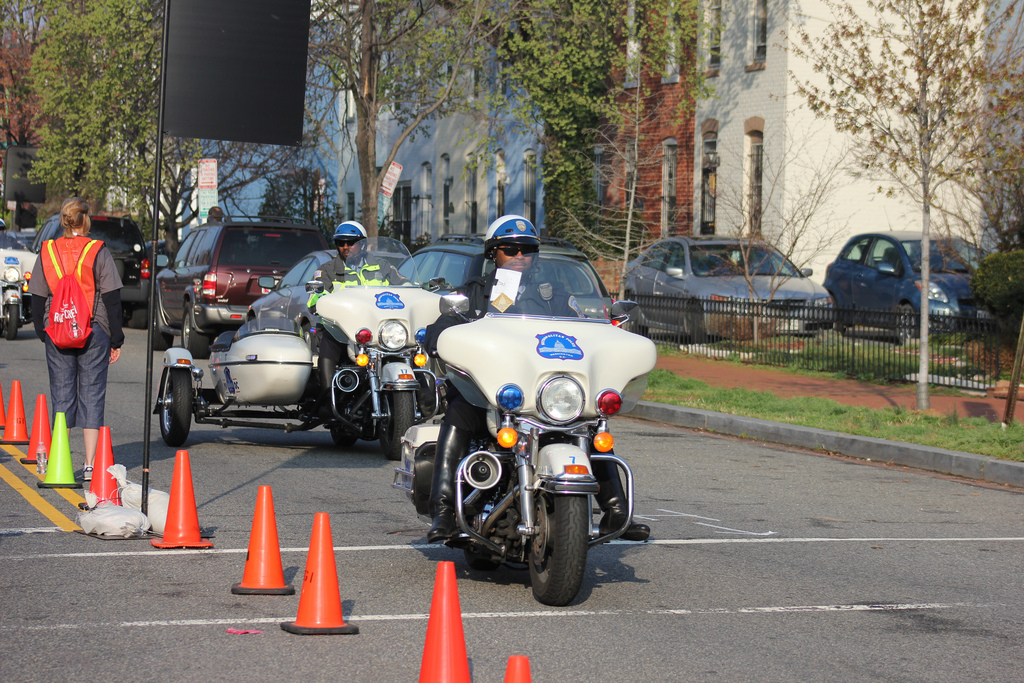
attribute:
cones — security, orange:
[29, 402, 487, 679]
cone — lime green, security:
[51, 415, 73, 509]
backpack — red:
[36, 255, 112, 374]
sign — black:
[156, 72, 306, 131]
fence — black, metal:
[699, 286, 833, 390]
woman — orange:
[38, 221, 123, 507]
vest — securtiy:
[31, 227, 99, 333]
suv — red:
[118, 186, 278, 349]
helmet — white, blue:
[496, 202, 516, 272]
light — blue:
[468, 368, 527, 444]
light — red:
[589, 394, 618, 423]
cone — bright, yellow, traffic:
[16, 385, 92, 513]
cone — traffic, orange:
[81, 433, 321, 587]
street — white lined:
[621, 426, 967, 664]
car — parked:
[614, 225, 844, 351]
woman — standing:
[31, 201, 96, 441]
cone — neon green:
[31, 379, 129, 520]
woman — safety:
[25, 206, 192, 496]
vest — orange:
[25, 208, 119, 329]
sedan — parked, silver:
[591, 214, 797, 385]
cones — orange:
[90, 424, 480, 658]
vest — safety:
[35, 240, 120, 325]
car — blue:
[843, 212, 995, 353]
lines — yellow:
[0, 430, 173, 565]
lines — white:
[621, 454, 978, 554]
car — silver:
[610, 212, 861, 347]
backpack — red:
[40, 258, 164, 379]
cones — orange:
[176, 458, 364, 608]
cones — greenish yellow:
[18, 415, 146, 515]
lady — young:
[20, 178, 235, 457]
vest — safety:
[12, 230, 134, 334]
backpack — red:
[42, 258, 142, 367]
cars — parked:
[227, 190, 716, 342]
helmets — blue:
[309, 204, 595, 269]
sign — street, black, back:
[145, 27, 388, 174]